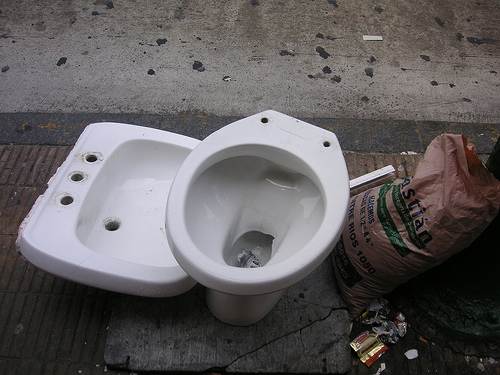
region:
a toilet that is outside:
[72, 57, 418, 358]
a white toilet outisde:
[169, 102, 358, 352]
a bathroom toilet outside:
[143, 63, 385, 305]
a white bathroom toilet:
[141, 103, 357, 324]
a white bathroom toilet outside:
[139, 89, 379, 371]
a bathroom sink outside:
[29, 89, 274, 371]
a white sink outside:
[47, 98, 206, 368]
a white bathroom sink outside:
[4, 120, 299, 371]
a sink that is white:
[39, 66, 319, 358]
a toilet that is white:
[137, 104, 349, 374]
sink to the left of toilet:
[16, 120, 193, 298]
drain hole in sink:
[105, 216, 121, 228]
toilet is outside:
[1, 1, 497, 373]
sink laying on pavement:
[16, 120, 202, 298]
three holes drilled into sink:
[57, 148, 97, 205]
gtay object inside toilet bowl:
[236, 250, 258, 268]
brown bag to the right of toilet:
[323, 133, 499, 319]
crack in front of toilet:
[218, 305, 350, 372]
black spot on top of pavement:
[193, 59, 204, 71]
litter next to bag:
[346, 300, 419, 374]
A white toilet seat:
[183, 107, 325, 302]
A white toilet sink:
[36, 118, 182, 323]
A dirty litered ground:
[318, 301, 470, 371]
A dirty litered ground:
[44, 21, 211, 106]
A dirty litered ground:
[157, 21, 243, 101]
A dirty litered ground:
[260, 9, 369, 106]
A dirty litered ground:
[369, 14, 486, 117]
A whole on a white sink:
[100, 209, 125, 244]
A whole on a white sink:
[58, 188, 72, 205]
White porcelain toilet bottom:
[164, 88, 353, 330]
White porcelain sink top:
[16, 120, 213, 300]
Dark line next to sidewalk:
[1, 100, 496, 162]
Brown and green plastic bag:
[326, 123, 498, 323]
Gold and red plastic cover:
[348, 328, 388, 365]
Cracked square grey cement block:
[107, 260, 353, 374]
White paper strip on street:
[359, 28, 387, 43]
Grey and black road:
[4, 0, 498, 117]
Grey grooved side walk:
[0, 143, 498, 374]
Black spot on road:
[148, 31, 168, 45]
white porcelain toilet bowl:
[162, 105, 353, 330]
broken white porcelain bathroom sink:
[10, 115, 210, 302]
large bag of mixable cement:
[326, 129, 498, 326]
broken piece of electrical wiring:
[339, 293, 438, 373]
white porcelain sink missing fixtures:
[12, 117, 209, 304]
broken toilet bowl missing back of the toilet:
[162, 105, 355, 328]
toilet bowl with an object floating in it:
[160, 105, 357, 336]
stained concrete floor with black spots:
[132, 18, 347, 98]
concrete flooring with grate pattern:
[30, 296, 96, 373]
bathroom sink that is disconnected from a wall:
[12, 119, 209, 301]